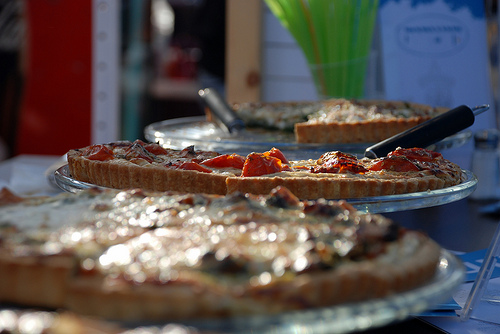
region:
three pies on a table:
[1, 63, 481, 321]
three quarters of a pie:
[131, 80, 476, 157]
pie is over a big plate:
[143, 78, 480, 155]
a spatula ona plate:
[191, 78, 283, 150]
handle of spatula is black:
[194, 74, 243, 129]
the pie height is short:
[59, 128, 460, 200]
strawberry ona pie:
[181, 138, 296, 178]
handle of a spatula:
[350, 89, 492, 161]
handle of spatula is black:
[366, 95, 495, 170]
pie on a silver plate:
[13, 177, 471, 327]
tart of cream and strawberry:
[41, 125, 488, 208]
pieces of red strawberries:
[203, 140, 290, 176]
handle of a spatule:
[364, 96, 492, 159]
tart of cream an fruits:
[6, 174, 468, 332]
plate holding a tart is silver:
[2, 245, 467, 330]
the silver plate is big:
[0, 259, 483, 329]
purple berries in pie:
[250, 180, 350, 215]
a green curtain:
[266, 5, 391, 95]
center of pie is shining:
[26, 180, 332, 280]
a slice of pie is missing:
[191, 71, 461, 144]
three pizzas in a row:
[23, 45, 489, 330]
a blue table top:
[449, 214, 496, 323]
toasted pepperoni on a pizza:
[109, 134, 452, 185]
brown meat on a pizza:
[100, 189, 412, 282]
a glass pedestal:
[326, 302, 420, 327]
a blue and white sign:
[382, 4, 497, 102]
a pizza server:
[199, 88, 304, 163]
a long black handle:
[366, 105, 492, 153]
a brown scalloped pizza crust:
[89, 162, 156, 189]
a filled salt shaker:
[473, 127, 498, 212]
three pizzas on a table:
[52, 72, 442, 329]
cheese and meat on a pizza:
[103, 187, 363, 280]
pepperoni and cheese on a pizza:
[100, 122, 427, 184]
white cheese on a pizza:
[270, 95, 415, 127]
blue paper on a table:
[460, 250, 497, 310]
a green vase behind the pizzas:
[273, 2, 384, 87]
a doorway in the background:
[129, 8, 221, 103]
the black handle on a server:
[351, 100, 476, 151]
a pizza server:
[195, 87, 282, 162]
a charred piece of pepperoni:
[317, 148, 357, 173]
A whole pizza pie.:
[8, 190, 448, 309]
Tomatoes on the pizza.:
[76, 134, 441, 173]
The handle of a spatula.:
[366, 96, 479, 161]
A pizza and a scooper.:
[212, 98, 429, 140]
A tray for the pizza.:
[329, 181, 481, 208]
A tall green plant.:
[271, 1, 383, 101]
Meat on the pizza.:
[193, 243, 338, 265]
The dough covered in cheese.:
[6, 211, 192, 263]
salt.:
[467, 127, 499, 197]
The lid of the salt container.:
[463, 127, 498, 151]